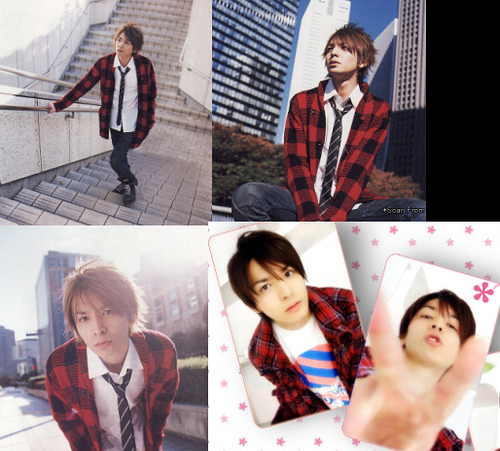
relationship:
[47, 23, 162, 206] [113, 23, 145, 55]
person has hair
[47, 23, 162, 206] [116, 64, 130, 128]
person wearing a tie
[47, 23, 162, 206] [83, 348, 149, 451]
person wearing a shirt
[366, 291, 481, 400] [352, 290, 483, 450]
peace sign made with fingers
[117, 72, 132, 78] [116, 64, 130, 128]
knot on tie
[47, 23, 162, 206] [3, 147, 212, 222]
person walking up stairs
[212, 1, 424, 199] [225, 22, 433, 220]
buildings are behind man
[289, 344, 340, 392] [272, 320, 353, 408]
design on shirt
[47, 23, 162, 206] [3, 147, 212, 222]
person standing on stairs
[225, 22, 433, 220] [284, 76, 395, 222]
man wearing a shirt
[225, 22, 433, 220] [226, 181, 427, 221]
man wearing jeans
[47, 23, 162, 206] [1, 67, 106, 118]
person holding rail